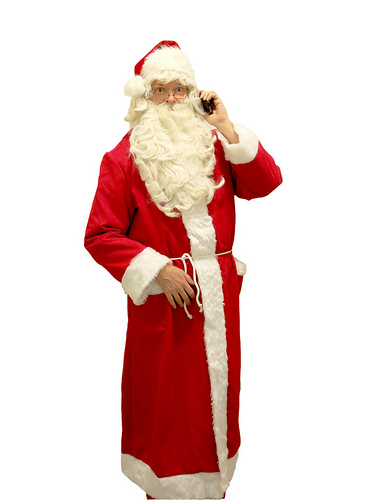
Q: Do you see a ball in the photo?
A: Yes, there is a ball.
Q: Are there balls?
A: Yes, there is a ball.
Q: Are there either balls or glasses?
A: Yes, there is a ball.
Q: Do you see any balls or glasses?
A: Yes, there is a ball.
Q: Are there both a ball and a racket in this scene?
A: No, there is a ball but no rackets.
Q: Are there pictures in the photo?
A: No, there are no pictures.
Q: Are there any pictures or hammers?
A: No, there are no pictures or hammers.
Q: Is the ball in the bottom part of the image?
A: No, the ball is in the top of the image.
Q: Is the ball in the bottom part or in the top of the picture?
A: The ball is in the top of the image.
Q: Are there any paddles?
A: No, there are no paddles.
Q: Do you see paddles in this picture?
A: No, there are no paddles.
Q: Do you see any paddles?
A: No, there are no paddles.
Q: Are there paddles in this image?
A: No, there are no paddles.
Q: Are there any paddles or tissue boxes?
A: No, there are no paddles or tissue boxes.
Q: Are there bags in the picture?
A: No, there are no bags.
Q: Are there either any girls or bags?
A: No, there are no bags or girls.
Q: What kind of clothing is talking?
A: The clothing is a costume.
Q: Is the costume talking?
A: Yes, the costume is talking.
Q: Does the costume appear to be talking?
A: Yes, the costume is talking.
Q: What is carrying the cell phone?
A: The costume is carrying the cell phone.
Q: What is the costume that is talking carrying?
A: The costume is carrying a cellphone.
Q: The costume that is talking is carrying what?
A: The costume is carrying a cellphone.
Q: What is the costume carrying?
A: The costume is carrying a cellphone.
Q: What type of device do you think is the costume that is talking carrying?
A: The costume is carrying a mobile phone.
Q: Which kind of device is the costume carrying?
A: The costume is carrying a mobile phone.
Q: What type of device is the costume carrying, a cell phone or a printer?
A: The costume is carrying a cell phone.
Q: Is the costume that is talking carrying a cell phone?
A: Yes, the costume is carrying a cell phone.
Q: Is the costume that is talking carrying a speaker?
A: No, the costume is carrying a cell phone.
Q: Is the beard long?
A: Yes, the beard is long.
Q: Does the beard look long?
A: Yes, the beard is long.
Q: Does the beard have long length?
A: Yes, the beard is long.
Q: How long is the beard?
A: The beard is long.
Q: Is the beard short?
A: No, the beard is long.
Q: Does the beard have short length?
A: No, the beard is long.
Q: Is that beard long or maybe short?
A: The beard is long.